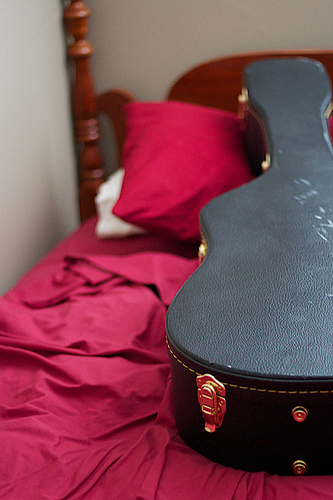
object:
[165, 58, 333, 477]
guitar case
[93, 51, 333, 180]
head board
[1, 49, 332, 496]
bed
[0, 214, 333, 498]
sheets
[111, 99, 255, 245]
pillow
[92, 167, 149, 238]
pillow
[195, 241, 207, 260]
latch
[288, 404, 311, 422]
stands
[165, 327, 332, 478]
bottom of case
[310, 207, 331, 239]
scruffs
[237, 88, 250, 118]
piece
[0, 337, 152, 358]
wrinkles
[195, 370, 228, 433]
grommets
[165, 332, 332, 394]
stitching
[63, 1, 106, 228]
bed post